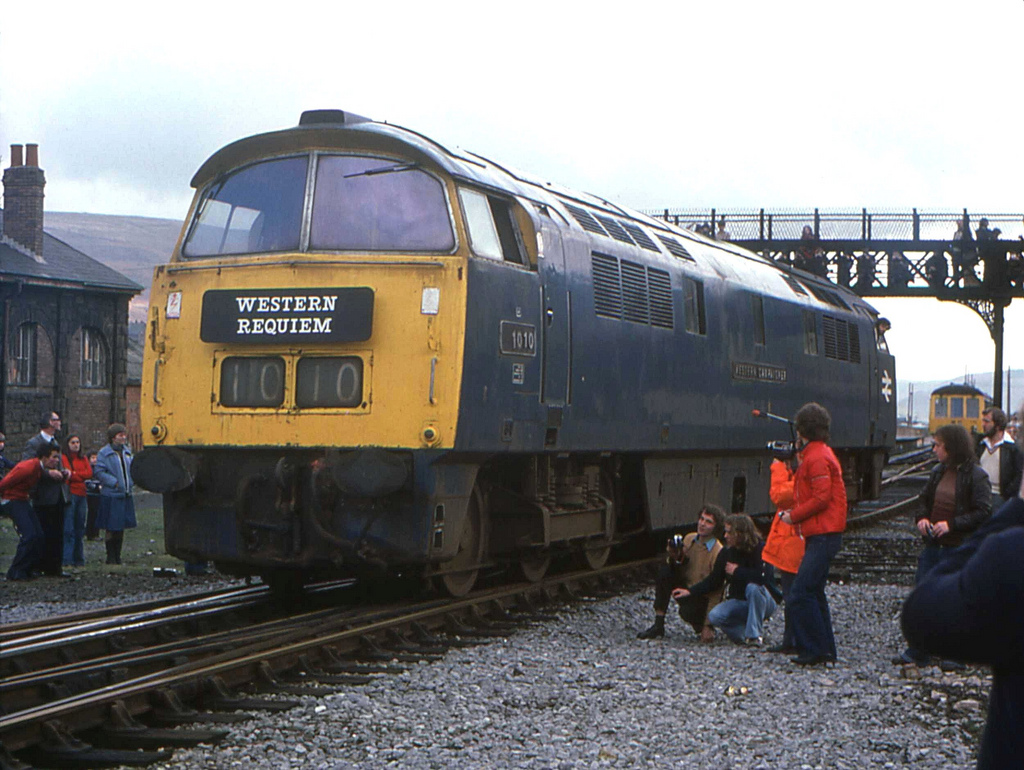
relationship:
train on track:
[132, 100, 902, 600] [11, 537, 685, 747]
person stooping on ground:
[641, 504, 721, 638] [310, 595, 993, 766]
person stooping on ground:
[705, 513, 775, 644] [310, 595, 993, 766]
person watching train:
[85, 420, 141, 568] [132, 100, 902, 600]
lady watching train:
[912, 424, 999, 592] [132, 100, 902, 600]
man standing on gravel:
[973, 404, 1014, 508] [158, 498, 1012, 764]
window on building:
[68, 324, 118, 404] [9, 136, 134, 481]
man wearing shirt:
[970, 397, 1022, 495] [976, 436, 1013, 494]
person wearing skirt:
[93, 421, 139, 566] [96, 494, 142, 532]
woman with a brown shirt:
[889, 422, 991, 668] [942, 486, 968, 569]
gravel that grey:
[484, 576, 893, 770] [469, 643, 582, 770]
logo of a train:
[218, 298, 357, 346] [437, 254, 643, 490]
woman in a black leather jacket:
[875, 388, 981, 704] [963, 455, 992, 587]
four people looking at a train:
[627, 371, 1021, 635] [542, 276, 694, 432]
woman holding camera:
[889, 422, 991, 668] [903, 509, 949, 620]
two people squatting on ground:
[629, 505, 768, 657] [244, 578, 865, 770]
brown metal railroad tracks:
[43, 611, 190, 726] [33, 596, 118, 728]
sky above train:
[665, 94, 860, 174] [188, 124, 681, 492]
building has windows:
[0, 199, 156, 388] [11, 325, 48, 384]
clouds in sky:
[386, 16, 642, 114] [2, 3, 990, 211]